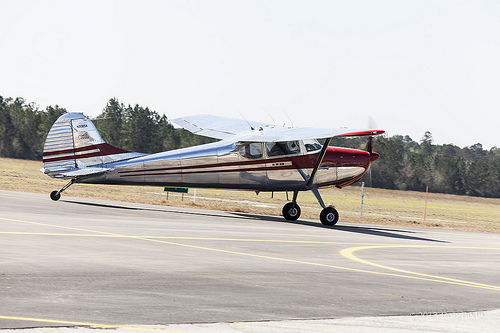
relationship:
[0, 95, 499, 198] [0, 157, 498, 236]
trees behind field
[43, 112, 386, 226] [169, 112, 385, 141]
airplane has wings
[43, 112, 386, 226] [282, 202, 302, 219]
airplane has wheel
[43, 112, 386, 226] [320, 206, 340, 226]
airplane has wheel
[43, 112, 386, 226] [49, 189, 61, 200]
airplane has wheel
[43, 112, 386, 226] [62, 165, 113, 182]
airplane has tail wing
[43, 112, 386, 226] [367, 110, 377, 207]
airplane has propeller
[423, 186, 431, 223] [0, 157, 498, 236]
post in field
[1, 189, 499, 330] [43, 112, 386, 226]
runway under airplane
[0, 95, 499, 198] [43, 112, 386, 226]
trees behind airplane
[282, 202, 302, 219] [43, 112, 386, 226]
wheel beneath airplane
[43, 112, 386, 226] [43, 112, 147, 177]
airplane has tail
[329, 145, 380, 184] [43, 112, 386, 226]
nose of airplane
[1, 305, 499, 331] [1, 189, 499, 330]
edge of runway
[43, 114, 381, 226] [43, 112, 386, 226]
side of airplane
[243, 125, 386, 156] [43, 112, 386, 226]
wing part of airplane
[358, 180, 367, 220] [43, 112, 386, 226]
post next to airplane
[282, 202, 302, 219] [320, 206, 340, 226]
wheel next to wheel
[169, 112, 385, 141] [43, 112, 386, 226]
wings part of airplane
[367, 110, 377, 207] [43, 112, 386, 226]
propeller attached to airplane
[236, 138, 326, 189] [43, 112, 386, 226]
cockpit of airplane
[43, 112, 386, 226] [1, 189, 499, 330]
airplane sitting on runway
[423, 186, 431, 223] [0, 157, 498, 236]
post sticking out of field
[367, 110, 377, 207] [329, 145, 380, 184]
propeller attached to nose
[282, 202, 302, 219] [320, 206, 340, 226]
wheel to left of wheel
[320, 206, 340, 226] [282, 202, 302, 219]
wheel to right of wheel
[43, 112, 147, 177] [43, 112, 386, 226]
tail part of airplane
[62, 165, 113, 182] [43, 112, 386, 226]
tail wing attached to airplane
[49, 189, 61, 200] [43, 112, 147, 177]
wheel under tail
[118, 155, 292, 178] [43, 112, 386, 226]
stripes painted on airplane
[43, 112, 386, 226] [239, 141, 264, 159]
airplane has window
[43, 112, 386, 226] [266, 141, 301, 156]
airplane has window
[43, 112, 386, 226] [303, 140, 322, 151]
airplane has window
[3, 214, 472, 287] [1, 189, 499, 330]
line painted on runway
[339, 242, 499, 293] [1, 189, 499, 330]
circle painted on runway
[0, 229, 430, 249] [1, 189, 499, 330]
line painted on runway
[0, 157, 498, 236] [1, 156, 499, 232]
field covered in grass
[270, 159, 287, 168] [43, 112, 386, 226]
writing painted on airplane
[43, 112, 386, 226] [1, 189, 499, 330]
airplane on top of runway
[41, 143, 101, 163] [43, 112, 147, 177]
stripes painted on tail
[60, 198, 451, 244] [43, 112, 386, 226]
shadow of airplane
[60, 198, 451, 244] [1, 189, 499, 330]
shadow on top of runway